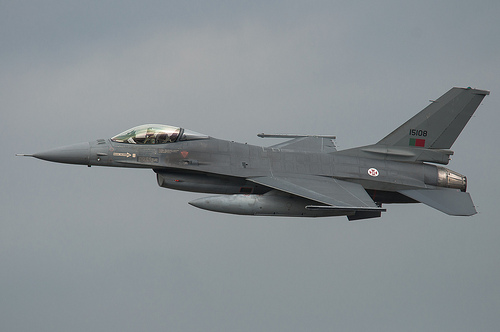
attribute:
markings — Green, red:
[408, 128, 427, 146]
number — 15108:
[402, 123, 430, 139]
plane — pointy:
[14, 84, 491, 221]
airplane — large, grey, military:
[28, 67, 491, 239]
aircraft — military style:
[83, 67, 450, 273]